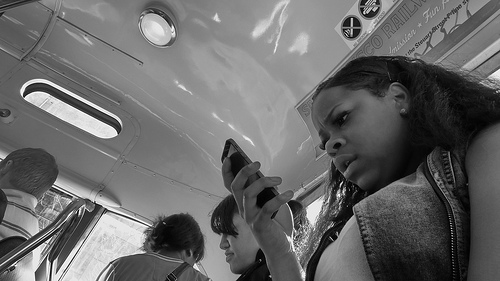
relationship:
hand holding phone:
[221, 155, 295, 250] [220, 139, 278, 219]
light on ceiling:
[133, 2, 178, 52] [57, 7, 259, 84]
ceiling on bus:
[57, 7, 259, 84] [6, 4, 498, 274]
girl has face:
[201, 51, 499, 278] [299, 81, 424, 193]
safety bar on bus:
[3, 194, 88, 268] [1, 4, 322, 273]